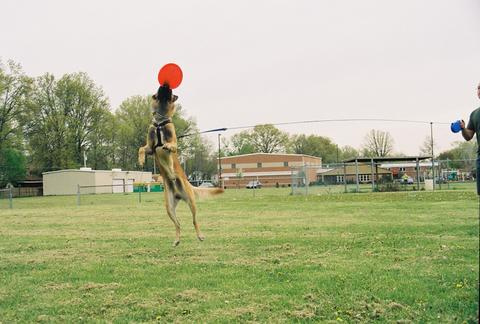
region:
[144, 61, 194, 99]
red Frisbee caught by brown dog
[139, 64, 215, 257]
brown dog catching red Frisbee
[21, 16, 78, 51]
white clouds in blue sky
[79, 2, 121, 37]
white clouds in blue sky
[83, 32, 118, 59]
white clouds in blue sky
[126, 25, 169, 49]
white clouds in blue sky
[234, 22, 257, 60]
white clouds in blue sky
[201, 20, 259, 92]
white clouds in blue sky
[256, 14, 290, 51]
white clouds in blue sky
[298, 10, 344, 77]
white clouds in blue sky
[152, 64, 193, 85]
red Frisbee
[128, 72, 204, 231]
dog catching red Frisbee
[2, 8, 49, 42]
white clouds in blue sky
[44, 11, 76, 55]
white clouds in blue sky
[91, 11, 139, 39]
white clouds in blue sky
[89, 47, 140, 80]
white clouds in blue sky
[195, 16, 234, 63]
white clouds in blue sky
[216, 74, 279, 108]
white clouds in blue sky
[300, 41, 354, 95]
white clouds in blue sky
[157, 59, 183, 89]
Round red frisbee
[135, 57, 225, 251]
Dog in mid air catching frisbee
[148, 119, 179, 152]
Black harness on dog catching frisbee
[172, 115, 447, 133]
Black leash attached to harness on dog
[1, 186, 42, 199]
Brown wooden fence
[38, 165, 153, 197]
Beige metal building with white doors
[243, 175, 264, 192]
Vehicle parked in front of brick building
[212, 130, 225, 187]
Parking lot light pole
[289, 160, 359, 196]
Chain link fence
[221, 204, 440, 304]
Large grass covered area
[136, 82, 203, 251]
a dog in the air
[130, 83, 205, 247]
a dog jumping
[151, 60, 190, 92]
a red freebie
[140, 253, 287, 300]
green and brown grass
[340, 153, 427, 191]
a open building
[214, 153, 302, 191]
a brick bulding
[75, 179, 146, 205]
a chain link fence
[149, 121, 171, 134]
a black collar on the dog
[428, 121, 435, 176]
a metal light pole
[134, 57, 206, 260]
a dog catching a freebie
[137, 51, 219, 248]
Dog catching a frisbee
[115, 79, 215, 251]
The dog is in the air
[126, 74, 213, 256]
The dog jumped up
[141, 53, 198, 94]
The frisbee is red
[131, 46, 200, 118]
Frisbee in the dog's mouth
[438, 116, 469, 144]
The leash is blue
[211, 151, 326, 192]
Brick building in the background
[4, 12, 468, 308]
Photo taken during the day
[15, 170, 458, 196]
chain link fence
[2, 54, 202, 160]
Green leaves on the trees